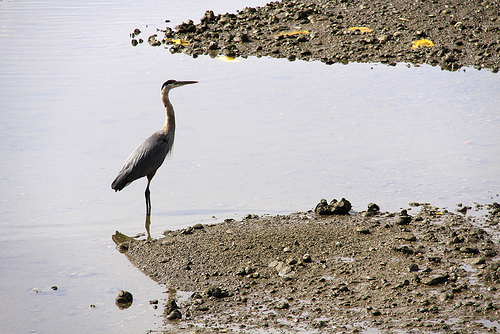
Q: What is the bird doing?
A: Standing.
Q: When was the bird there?
A: During the day.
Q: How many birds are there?
A: One.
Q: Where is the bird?
A: Close to the water.